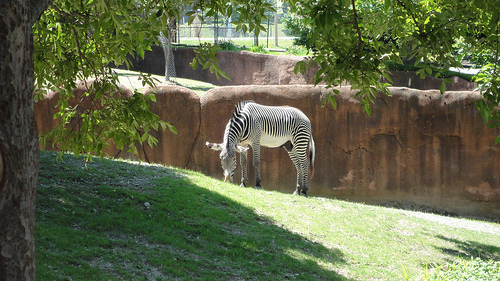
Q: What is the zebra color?
A: White and black.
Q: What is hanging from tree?
A: Leaves.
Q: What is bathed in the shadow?
A: Green and grey hill.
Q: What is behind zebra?
A: Wooden wall.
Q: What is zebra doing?
A: Eating.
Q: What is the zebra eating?
A: Grass.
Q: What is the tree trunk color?
A: Brown.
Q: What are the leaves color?
A: Green.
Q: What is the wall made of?
A: Cement.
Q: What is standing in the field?
A: A zebra.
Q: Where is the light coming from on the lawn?
A: The sun.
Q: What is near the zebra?
A: A fence.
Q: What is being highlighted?
A: A tree trunk.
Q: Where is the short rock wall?
A: Behind the zebra.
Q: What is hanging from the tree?
A: A branch with leaves.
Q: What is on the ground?
A: Green grass.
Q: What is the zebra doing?
A: Eating grass.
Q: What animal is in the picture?
A: A zebra.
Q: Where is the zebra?
A: At a zoo.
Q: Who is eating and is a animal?
A: The zebra.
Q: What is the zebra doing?
A: Eating.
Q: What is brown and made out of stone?
A: A wall.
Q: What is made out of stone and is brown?
A: A wall.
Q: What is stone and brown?
A: A wall.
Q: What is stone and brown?
A: A wall.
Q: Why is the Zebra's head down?
A: Eating grass.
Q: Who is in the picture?
A: Zebra.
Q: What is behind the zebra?
A: Rock wall.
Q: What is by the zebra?
A: Tree.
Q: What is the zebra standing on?
A: Grass.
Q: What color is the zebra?
A: Black and white.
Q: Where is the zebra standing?
A: Hill.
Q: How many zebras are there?
A: One.